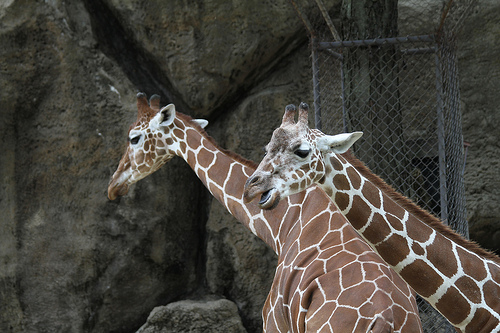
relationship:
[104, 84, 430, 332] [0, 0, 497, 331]
giraffe in rock pen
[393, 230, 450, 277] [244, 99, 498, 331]
line on giraffe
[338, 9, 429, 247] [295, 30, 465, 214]
tree trunk inside fence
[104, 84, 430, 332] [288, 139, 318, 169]
giraffe has eye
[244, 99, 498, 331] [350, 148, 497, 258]
giraffe has hair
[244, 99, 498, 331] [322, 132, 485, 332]
giraffe has neck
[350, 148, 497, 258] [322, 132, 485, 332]
hair on neck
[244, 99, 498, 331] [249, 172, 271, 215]
giraffe has mouth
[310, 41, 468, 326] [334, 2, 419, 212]
fence around tree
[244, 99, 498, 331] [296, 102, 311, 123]
giraffe has horns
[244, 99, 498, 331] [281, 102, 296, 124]
giraffe has horns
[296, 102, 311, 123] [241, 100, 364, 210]
horns on head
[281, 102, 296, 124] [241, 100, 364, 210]
horns on head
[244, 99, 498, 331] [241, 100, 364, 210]
giraffe on head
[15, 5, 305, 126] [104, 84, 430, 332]
rocks behind giraffe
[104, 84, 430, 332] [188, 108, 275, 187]
giraffe has mane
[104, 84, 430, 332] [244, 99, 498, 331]
giraffe stands with giraffe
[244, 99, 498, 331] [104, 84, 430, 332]
giraffe stands with giraffe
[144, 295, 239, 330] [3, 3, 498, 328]
stone in enclosure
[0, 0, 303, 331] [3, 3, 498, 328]
stone in enclosure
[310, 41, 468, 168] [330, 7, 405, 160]
fence made of tree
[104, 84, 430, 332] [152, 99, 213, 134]
giraffe has ears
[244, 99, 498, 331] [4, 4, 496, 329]
giraffe in zoo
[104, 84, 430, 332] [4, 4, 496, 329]
giraffe in zoo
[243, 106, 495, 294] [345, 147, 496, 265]
neck has mane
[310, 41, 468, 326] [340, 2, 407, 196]
fence on tree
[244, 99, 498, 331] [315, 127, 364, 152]
giraffe has a ear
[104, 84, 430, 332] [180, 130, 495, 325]
giraffe have necks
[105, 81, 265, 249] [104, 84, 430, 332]
head on giraffe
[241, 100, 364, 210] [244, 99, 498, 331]
head on giraffe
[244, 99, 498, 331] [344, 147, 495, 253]
giraffe on rights mane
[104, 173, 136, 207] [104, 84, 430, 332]
mouth on giraffe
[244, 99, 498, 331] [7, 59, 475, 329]
giraffe at zoo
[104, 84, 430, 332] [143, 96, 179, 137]
giraffe has ear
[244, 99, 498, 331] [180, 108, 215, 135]
giraffe has ear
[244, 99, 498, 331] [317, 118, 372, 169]
giraffe has ear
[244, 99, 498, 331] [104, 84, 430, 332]
giraffe next to giraffe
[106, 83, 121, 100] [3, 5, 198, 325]
spot on stone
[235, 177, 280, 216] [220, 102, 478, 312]
open mouth on giraffe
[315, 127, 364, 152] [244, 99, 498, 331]
ear on giraffe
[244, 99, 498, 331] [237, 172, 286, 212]
giraffe with open mouth